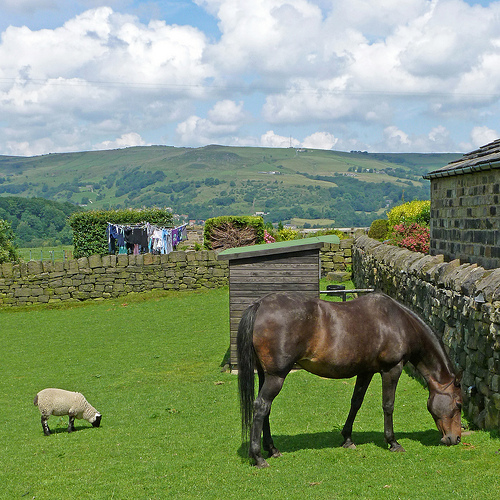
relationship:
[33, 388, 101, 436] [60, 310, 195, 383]
animal in a field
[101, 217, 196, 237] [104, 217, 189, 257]
clothes line with many clothes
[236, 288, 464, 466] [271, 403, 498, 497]
animal eating grass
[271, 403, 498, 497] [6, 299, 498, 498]
grass in field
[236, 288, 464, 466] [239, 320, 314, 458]
animal has leg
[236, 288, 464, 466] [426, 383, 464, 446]
animal has head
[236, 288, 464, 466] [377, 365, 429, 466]
animal has legs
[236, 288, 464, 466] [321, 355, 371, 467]
animal has legs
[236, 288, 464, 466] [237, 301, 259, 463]
animal has tail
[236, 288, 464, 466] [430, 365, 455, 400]
animal has ear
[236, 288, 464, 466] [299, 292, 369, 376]
animal has body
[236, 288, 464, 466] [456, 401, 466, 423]
animal has eye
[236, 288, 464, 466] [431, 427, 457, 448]
animal has mouth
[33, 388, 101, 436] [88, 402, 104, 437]
animal has head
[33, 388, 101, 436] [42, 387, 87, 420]
animal has body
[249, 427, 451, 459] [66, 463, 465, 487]
shadow on ground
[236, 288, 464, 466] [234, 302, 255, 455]
animal has tail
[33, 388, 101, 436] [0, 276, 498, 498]
animal grazes grass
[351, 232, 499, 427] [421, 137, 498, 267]
wall between house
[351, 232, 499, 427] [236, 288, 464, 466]
wall between animal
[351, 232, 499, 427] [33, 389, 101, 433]
wall between animal